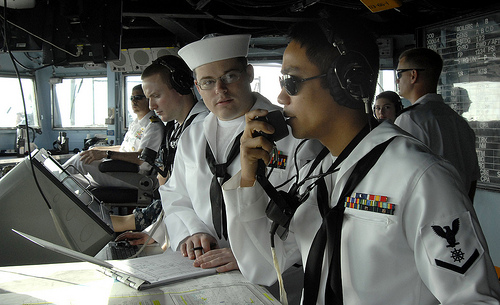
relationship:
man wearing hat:
[157, 31, 323, 274] [178, 32, 252, 72]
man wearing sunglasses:
[220, 14, 499, 304] [278, 67, 326, 94]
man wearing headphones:
[220, 14, 499, 304] [150, 58, 195, 95]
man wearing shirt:
[220, 14, 499, 304] [220, 119, 498, 302]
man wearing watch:
[63, 84, 165, 187] [106, 150, 111, 159]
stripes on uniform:
[340, 192, 396, 218] [225, 126, 484, 303]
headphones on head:
[324, 22, 376, 99] [265, 23, 390, 154]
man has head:
[220, 14, 499, 304] [265, 23, 390, 154]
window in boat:
[47, 71, 115, 133] [0, 0, 499, 302]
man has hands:
[157, 31, 323, 274] [174, 233, 238, 273]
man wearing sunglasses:
[220, 14, 499, 304] [274, 72, 327, 94]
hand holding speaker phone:
[233, 115, 287, 170] [249, 107, 299, 232]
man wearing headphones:
[220, 14, 499, 304] [313, 31, 375, 105]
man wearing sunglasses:
[220, 14, 499, 304] [276, 68, 330, 99]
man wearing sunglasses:
[220, 14, 499, 304] [275, 58, 334, 98]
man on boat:
[220, 14, 499, 304] [10, 10, 492, 250]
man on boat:
[157, 31, 323, 274] [10, 10, 492, 250]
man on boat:
[110, 54, 209, 254] [10, 10, 492, 250]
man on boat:
[79, 84, 166, 173] [10, 10, 492, 250]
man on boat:
[400, 46, 466, 148] [10, 10, 492, 250]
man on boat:
[376, 87, 410, 126] [10, 10, 492, 250]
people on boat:
[37, 22, 497, 303] [1, 0, 486, 303]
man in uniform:
[220, 14, 499, 304] [225, 126, 484, 303]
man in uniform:
[79, 84, 166, 173] [115, 110, 166, 160]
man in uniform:
[157, 30, 321, 267] [158, 30, 303, 247]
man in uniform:
[112, 54, 209, 254] [160, 95, 207, 176]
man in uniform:
[395, 47, 483, 205] [390, 91, 482, 201]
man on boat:
[220, 14, 499, 304] [1, 0, 486, 303]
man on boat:
[157, 31, 323, 274] [1, 0, 486, 303]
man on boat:
[110, 54, 209, 254] [1, 0, 486, 303]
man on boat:
[79, 84, 166, 173] [1, 0, 486, 303]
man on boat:
[395, 47, 483, 205] [1, 0, 486, 303]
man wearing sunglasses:
[263, 1, 446, 222] [258, 19, 488, 234]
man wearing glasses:
[157, 31, 323, 274] [190, 71, 252, 90]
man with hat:
[157, 31, 323, 274] [178, 32, 251, 72]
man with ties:
[220, 14, 499, 304] [198, 127, 405, 299]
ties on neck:
[198, 127, 405, 299] [311, 104, 404, 171]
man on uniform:
[157, 31, 323, 274] [161, 110, 281, 265]